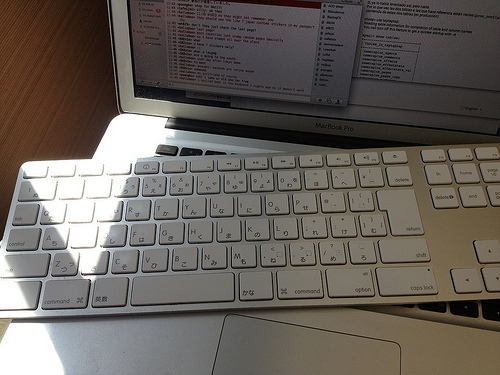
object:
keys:
[17, 165, 413, 202]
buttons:
[450, 239, 500, 293]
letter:
[111, 249, 139, 274]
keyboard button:
[421, 149, 447, 162]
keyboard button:
[425, 164, 452, 185]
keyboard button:
[431, 186, 459, 208]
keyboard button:
[452, 163, 480, 184]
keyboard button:
[458, 185, 487, 207]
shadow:
[0, 0, 500, 374]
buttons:
[0, 146, 500, 310]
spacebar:
[130, 271, 235, 305]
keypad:
[419, 146, 500, 294]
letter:
[218, 219, 243, 243]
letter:
[172, 247, 198, 271]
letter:
[210, 196, 234, 217]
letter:
[278, 170, 302, 191]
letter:
[125, 199, 151, 221]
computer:
[0, 0, 500, 375]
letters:
[0, 146, 500, 310]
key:
[111, 248, 139, 274]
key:
[261, 243, 286, 267]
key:
[125, 199, 151, 220]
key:
[349, 240, 377, 265]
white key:
[40, 202, 67, 224]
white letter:
[188, 219, 214, 242]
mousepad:
[212, 313, 401, 375]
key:
[245, 218, 270, 241]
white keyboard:
[0, 142, 500, 322]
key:
[210, 196, 233, 218]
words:
[130, 0, 500, 99]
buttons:
[17, 150, 412, 202]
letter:
[231, 244, 257, 268]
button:
[376, 189, 425, 236]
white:
[127, 199, 154, 220]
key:
[96, 200, 124, 222]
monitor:
[127, 0, 500, 136]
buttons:
[396, 300, 500, 321]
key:
[6, 228, 41, 251]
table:
[0, 0, 500, 375]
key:
[154, 197, 179, 220]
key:
[67, 201, 95, 223]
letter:
[154, 198, 179, 220]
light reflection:
[19, 113, 173, 284]